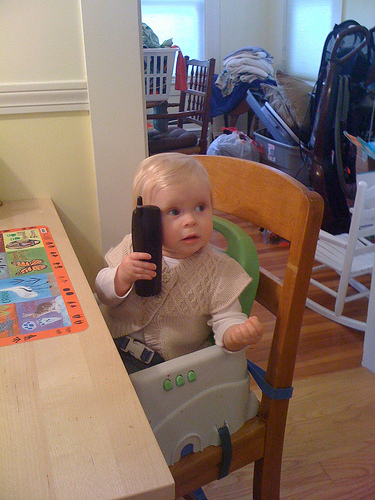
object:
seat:
[102, 212, 275, 465]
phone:
[130, 194, 163, 297]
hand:
[118, 252, 157, 284]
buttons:
[163, 378, 174, 393]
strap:
[246, 354, 293, 401]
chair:
[133, 155, 325, 499]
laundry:
[140, 16, 186, 94]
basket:
[140, 45, 179, 102]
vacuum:
[308, 22, 374, 222]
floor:
[252, 246, 372, 462]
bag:
[205, 129, 261, 163]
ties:
[222, 133, 246, 148]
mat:
[0, 224, 87, 351]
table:
[0, 178, 178, 500]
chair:
[297, 164, 375, 332]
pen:
[310, 18, 374, 206]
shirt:
[98, 232, 263, 351]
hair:
[131, 151, 211, 213]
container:
[253, 124, 311, 191]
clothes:
[225, 49, 273, 80]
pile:
[224, 47, 273, 87]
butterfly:
[10, 259, 48, 276]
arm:
[93, 238, 130, 310]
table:
[143, 98, 168, 113]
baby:
[94, 152, 259, 351]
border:
[44, 226, 87, 325]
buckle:
[119, 328, 155, 372]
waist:
[104, 327, 169, 367]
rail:
[323, 28, 354, 167]